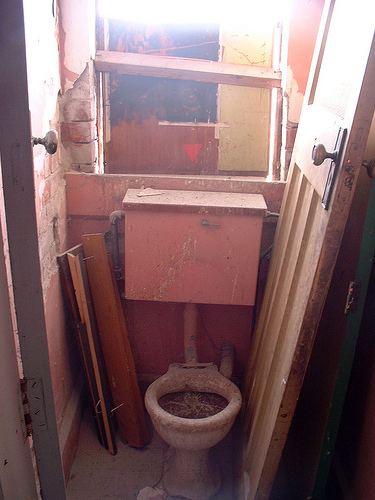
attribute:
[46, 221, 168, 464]
panels — wood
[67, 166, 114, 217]
paint — peeling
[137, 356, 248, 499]
toilet — rusted, white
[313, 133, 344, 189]
handle — metal, door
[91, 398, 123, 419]
mails — exposed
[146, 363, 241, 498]
toilet bowl — rusted, filthy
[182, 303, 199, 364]
pipe — toilet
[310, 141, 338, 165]
door knob — bronze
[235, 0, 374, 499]
door — wooden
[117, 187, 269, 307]
toilet tank — square, old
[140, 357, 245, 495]
toilet bowl — empty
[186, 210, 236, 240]
handle — toilet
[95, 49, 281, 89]
framing — broken, wood, construction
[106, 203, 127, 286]
pipe — metal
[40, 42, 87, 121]
paint — peeling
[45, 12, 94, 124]
paint — peeling